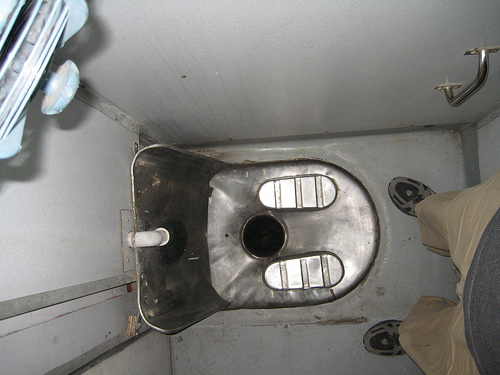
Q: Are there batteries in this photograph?
A: No, there are no batteries.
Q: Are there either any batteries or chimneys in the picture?
A: No, there are no batteries or chimneys.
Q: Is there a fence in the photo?
A: No, there are no fences.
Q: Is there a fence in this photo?
A: No, there are no fences.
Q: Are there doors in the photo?
A: Yes, there is a door.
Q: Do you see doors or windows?
A: Yes, there is a door.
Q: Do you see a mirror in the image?
A: No, there are no mirrors.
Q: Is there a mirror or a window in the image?
A: No, there are no mirrors or windows.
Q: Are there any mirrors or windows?
A: No, there are no mirrors or windows.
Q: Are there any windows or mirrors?
A: No, there are no mirrors or windows.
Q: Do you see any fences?
A: No, there are no fences.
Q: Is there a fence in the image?
A: No, there are no fences.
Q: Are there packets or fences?
A: No, there are no fences or packets.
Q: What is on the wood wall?
A: The pipe is on the wall.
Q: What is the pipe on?
A: The pipe is on the wall.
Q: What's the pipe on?
A: The pipe is on the wall.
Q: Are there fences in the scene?
A: No, there are no fences.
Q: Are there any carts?
A: No, there are no carts.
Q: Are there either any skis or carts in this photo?
A: No, there are no carts or skis.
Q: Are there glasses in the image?
A: No, there are no glasses.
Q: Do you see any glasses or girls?
A: No, there are no glasses or girls.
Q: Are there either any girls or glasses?
A: No, there are no glasses or girls.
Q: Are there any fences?
A: No, there are no fences.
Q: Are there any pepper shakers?
A: No, there are no pepper shakers.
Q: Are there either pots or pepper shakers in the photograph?
A: No, there are no pepper shakers or pots.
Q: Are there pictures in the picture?
A: No, there are no pictures.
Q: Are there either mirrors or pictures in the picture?
A: No, there are no pictures or mirrors.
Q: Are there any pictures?
A: No, there are no pictures.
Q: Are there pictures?
A: No, there are no pictures.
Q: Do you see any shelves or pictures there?
A: No, there are no pictures or shelves.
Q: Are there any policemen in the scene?
A: No, there are no policemen.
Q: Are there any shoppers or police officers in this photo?
A: No, there are no police officers or shoppers.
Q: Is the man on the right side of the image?
A: Yes, the man is on the right of the image.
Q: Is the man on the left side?
A: No, the man is on the right of the image.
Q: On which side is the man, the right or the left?
A: The man is on the right of the image.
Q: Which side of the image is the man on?
A: The man is on the right of the image.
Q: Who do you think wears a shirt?
A: The man wears a shirt.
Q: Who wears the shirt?
A: The man wears a shirt.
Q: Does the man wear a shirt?
A: Yes, the man wears a shirt.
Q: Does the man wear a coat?
A: No, the man wears a shirt.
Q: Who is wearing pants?
A: The man is wearing pants.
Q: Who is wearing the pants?
A: The man is wearing pants.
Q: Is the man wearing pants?
A: Yes, the man is wearing pants.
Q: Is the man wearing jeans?
A: No, the man is wearing pants.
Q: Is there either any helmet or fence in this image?
A: No, there are no fences or helmets.